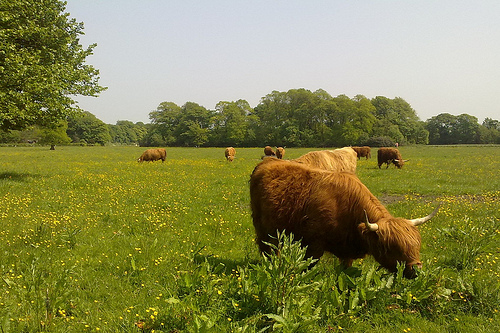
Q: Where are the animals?
A: The field.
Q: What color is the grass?
A: Green.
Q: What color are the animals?
A: Brown.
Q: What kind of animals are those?
A: Cows.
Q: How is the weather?
A: Overcast.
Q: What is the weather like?
A: Sunny.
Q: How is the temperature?
A: Warm.